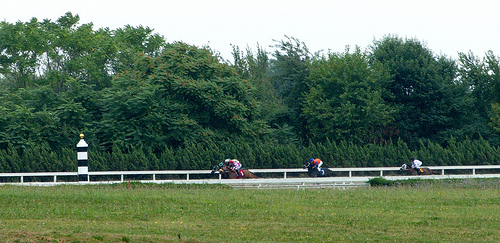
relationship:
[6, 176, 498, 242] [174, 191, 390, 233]
ground has part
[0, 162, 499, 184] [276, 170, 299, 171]
metal has part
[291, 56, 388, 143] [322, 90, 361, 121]
tree has part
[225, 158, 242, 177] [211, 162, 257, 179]
people on horse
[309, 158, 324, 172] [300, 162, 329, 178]
people on horse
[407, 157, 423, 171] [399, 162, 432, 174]
people on horse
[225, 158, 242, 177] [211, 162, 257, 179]
people riding horse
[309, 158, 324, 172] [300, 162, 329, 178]
people riding horse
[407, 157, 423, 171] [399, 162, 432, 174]
people riding horse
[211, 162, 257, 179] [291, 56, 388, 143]
horse close to tree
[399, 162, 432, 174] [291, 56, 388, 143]
horse close to tree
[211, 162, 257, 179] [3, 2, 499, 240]
horse on day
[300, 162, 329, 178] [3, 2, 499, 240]
horse on day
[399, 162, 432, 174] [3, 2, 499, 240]
horse on day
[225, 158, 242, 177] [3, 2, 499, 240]
people enjoying day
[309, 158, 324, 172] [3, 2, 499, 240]
people enjoying day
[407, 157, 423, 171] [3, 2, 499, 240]
people enjoying day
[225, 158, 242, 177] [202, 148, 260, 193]
people in front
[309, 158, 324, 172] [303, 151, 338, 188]
people in middle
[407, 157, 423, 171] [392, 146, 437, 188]
people in back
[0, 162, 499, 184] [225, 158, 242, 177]
metal next to people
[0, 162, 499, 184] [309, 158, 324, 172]
metal next to people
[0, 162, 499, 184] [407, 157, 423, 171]
metal next to people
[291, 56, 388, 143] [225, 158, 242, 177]
tree next to people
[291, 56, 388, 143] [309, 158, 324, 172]
tree next to people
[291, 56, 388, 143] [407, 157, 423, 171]
tree next to people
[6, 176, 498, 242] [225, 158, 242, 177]
field next to people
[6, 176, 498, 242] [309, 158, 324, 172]
field next to people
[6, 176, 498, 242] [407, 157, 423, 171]
field next to people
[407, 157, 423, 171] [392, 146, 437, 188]
people at back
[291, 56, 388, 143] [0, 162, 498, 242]
tree next to race track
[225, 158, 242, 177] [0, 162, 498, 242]
people on race track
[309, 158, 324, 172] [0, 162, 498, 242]
people on race track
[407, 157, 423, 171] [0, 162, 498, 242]
people on race track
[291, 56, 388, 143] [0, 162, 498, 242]
tree at side of race track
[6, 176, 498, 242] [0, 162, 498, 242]
ground near race track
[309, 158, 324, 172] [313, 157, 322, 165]
people wearing clothing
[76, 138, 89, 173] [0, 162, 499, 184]
post of metal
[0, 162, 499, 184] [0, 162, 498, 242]
metal on race track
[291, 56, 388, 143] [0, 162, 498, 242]
tree near race track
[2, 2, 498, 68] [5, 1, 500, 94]
sky at backgroud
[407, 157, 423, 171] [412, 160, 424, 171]
people wearing clothing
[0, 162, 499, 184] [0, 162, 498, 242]
metal in race track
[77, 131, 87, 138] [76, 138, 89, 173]
ball on top of post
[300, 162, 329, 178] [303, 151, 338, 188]
horse in middle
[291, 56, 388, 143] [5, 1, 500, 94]
tree in backgroud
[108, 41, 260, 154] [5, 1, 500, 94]
tree in backgroud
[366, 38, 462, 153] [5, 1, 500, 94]
tree in backgroud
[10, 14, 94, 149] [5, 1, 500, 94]
tree in backgroud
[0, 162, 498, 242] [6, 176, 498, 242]
race track full of grass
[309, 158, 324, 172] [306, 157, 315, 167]
people wearing helmet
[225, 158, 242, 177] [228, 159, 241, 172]
people wearing outfit